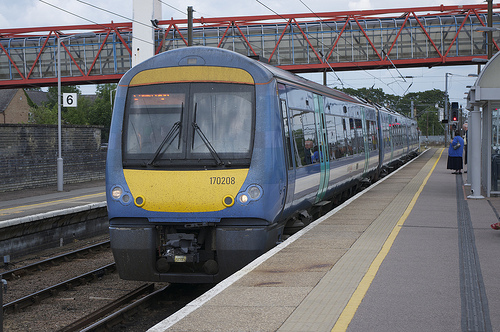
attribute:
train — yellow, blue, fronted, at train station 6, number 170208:
[117, 50, 398, 183]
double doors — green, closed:
[308, 99, 341, 188]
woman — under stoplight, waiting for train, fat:
[439, 120, 471, 174]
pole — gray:
[53, 30, 75, 191]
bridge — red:
[232, 8, 476, 91]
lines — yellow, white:
[371, 163, 451, 186]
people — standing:
[449, 118, 468, 165]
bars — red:
[353, 3, 462, 17]